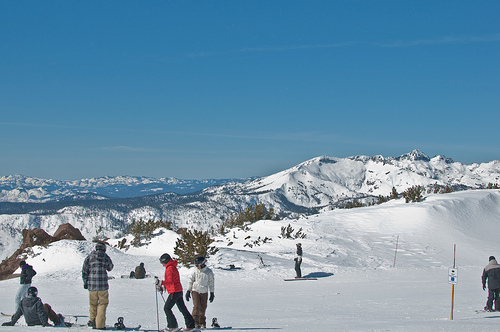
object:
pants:
[190, 290, 209, 330]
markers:
[448, 240, 459, 322]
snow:
[403, 301, 456, 326]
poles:
[152, 279, 159, 332]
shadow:
[298, 270, 334, 278]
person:
[0, 287, 66, 328]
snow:
[53, 290, 80, 311]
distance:
[10, 169, 131, 193]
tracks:
[366, 252, 393, 261]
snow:
[450, 200, 498, 232]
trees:
[111, 217, 226, 235]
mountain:
[173, 152, 500, 236]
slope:
[0, 248, 273, 332]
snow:
[251, 291, 290, 307]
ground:
[0, 261, 500, 331]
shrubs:
[233, 202, 271, 221]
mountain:
[0, 175, 314, 259]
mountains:
[0, 170, 292, 199]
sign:
[448, 266, 459, 284]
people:
[7, 237, 500, 330]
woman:
[154, 252, 194, 331]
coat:
[161, 260, 183, 294]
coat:
[186, 267, 215, 294]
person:
[187, 257, 217, 329]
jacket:
[81, 249, 114, 291]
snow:
[56, 273, 79, 286]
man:
[481, 256, 500, 311]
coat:
[483, 259, 500, 289]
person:
[295, 243, 303, 278]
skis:
[282, 277, 319, 281]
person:
[130, 262, 146, 279]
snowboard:
[121, 273, 151, 279]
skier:
[157, 252, 192, 332]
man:
[80, 243, 116, 331]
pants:
[84, 289, 110, 329]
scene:
[0, 10, 500, 332]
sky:
[0, 0, 500, 185]